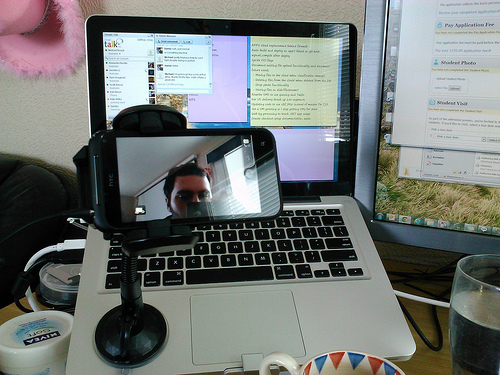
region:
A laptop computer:
[70, 14, 420, 371]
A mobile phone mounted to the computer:
[65, 105, 309, 362]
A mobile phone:
[79, 107, 291, 234]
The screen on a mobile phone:
[110, 129, 272, 220]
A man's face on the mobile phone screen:
[147, 156, 237, 226]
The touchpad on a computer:
[179, 290, 320, 367]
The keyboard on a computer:
[81, 196, 368, 298]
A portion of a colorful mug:
[244, 335, 424, 373]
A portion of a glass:
[439, 240, 498, 372]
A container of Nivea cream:
[2, 301, 90, 373]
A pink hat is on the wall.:
[0, 1, 85, 79]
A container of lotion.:
[0, 285, 81, 370]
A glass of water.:
[440, 250, 491, 372]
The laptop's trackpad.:
[176, 285, 311, 370]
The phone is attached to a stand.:
[55, 95, 301, 370]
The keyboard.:
[75, 190, 370, 290]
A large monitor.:
[350, 0, 490, 256]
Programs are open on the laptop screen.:
[100, 30, 345, 185]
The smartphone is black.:
[85, 115, 275, 225]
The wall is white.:
[10, 78, 68, 144]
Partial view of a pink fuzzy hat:
[0, 1, 85, 81]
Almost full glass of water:
[445, 252, 499, 374]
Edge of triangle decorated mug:
[260, 351, 413, 374]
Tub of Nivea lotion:
[3, 304, 79, 371]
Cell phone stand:
[91, 234, 178, 367]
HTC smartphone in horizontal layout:
[88, 129, 283, 224]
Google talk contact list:
[103, 31, 156, 116]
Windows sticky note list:
[250, 36, 337, 125]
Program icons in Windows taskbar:
[376, 208, 499, 233]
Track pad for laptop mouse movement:
[184, 289, 305, 365]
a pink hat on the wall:
[0, 0, 87, 83]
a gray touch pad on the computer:
[186, 285, 308, 367]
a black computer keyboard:
[101, 205, 368, 294]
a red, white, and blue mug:
[256, 350, 406, 373]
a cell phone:
[88, 127, 287, 232]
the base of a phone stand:
[91, 290, 177, 367]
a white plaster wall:
[0, 0, 365, 212]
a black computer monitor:
[352, 0, 499, 264]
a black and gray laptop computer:
[61, 12, 420, 373]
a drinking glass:
[442, 250, 499, 373]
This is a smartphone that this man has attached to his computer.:
[96, 122, 297, 271]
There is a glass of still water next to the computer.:
[448, 249, 498, 371]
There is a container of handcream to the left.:
[27, 315, 62, 372]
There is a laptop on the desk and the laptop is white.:
[80, 30, 400, 374]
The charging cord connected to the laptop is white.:
[406, 282, 426, 323]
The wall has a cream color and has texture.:
[21, 119, 42, 146]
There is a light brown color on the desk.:
[430, 360, 437, 369]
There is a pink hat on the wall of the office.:
[16, 15, 54, 52]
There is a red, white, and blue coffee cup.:
[301, 354, 331, 371]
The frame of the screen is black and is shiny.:
[366, 125, 397, 255]